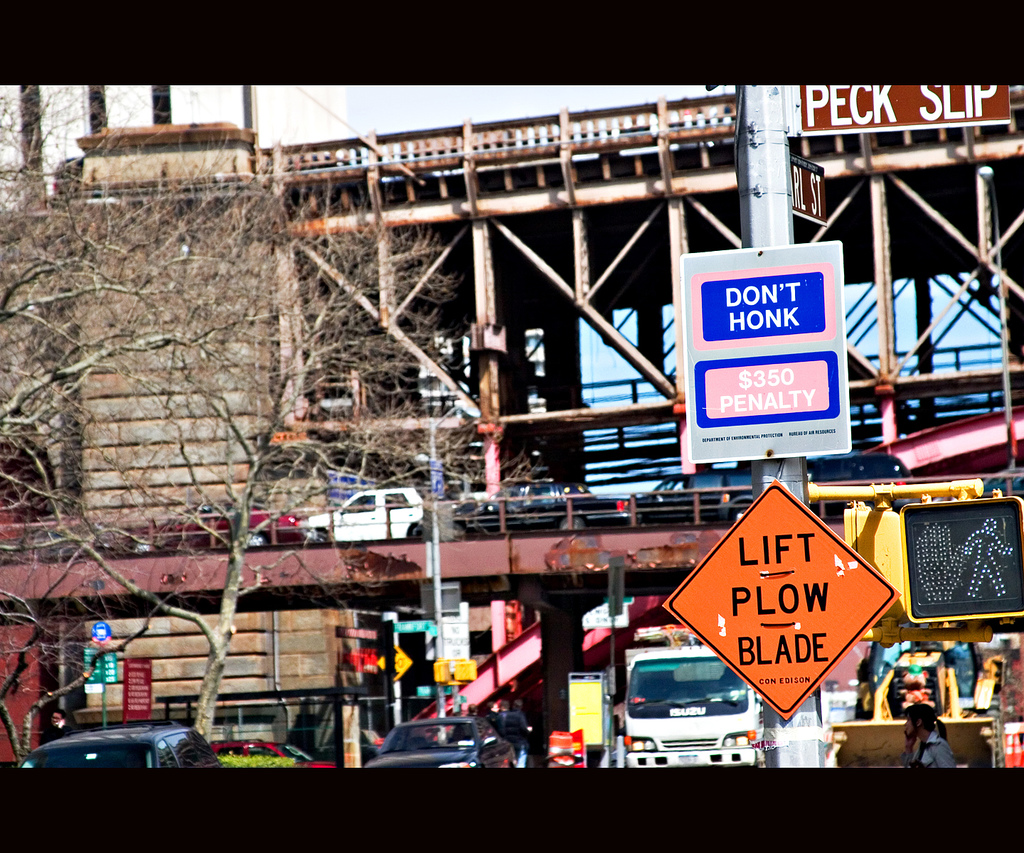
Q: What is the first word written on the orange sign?
A: LIFT.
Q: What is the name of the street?
A: PECK SLIP.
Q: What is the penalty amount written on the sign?
A: $350.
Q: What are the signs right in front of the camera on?
A: A pole.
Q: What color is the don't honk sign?
A: Blue.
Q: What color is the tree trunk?
A: Brown.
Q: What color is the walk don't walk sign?
A: Yellow.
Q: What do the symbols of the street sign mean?
A: Walk and don't walk.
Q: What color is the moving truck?
A: White.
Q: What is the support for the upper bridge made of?
A: Brick.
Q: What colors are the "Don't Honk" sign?
A: Blue, Pink, and Gray.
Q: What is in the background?
A: A bridge.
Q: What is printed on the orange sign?
A: "LIFT PLOW BLADE".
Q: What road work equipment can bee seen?
A: A backhoe.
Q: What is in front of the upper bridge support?
A: A small, bare tree.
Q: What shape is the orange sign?
A: Diamond.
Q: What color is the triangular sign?
A: Orange.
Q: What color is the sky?
A: Blue.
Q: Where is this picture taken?
A: A city bridge.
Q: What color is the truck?
A: White.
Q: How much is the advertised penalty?
A: 350 dollars.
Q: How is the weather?
A: Clear.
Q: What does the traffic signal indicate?
A: Walk.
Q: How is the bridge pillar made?
A: Of stone.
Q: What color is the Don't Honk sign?
A: Red and blue.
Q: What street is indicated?
A: Peck Slip.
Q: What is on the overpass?
A: Cars.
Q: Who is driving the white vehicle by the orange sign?
A: No indication.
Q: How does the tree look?
A: Barren.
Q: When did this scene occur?
A: During rush hour.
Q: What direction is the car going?
A: No indication.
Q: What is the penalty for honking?
A: $350.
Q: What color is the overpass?
A: Reddish-brown.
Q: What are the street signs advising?
A: Construction.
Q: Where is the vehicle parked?
A: On the side of the road.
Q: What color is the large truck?
A: White.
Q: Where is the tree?
A: On the side of the road.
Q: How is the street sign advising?
A: With its lights.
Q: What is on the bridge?
A: Cars.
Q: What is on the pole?
A: An orange sign.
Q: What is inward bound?
A: A white truck.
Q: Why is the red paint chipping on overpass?
A: Because of its age.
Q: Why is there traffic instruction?
A: To guide traffic safely for pedestrians.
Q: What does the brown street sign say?
A: Peck Slip.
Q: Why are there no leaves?
A: The trees are bare.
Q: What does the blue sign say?
A: Don't Honk.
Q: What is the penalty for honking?
A: $350.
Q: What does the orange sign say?
A: Lift Plow Blade.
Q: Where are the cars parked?
A: On a bridge in the background.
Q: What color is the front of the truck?
A: White.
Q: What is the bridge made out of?
A: Metal.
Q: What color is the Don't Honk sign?
A: Blue and white.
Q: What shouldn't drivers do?
A: Honk.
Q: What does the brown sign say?
A: Peck slip.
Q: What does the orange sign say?
A: Lift plow blade.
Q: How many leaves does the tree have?
A: 0.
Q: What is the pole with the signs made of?
A: Metal.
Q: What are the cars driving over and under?
A: Bridge.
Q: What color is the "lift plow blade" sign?
A: Orange.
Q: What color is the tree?
A: Brown.